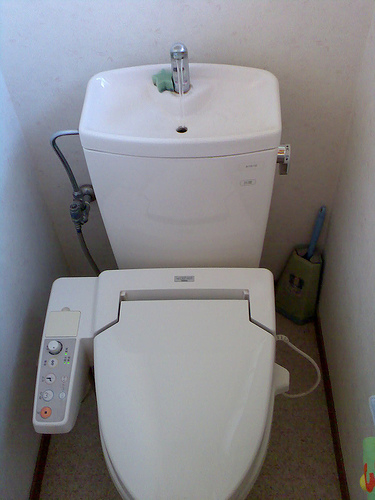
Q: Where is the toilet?
A: In a room.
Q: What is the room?
A: A toilet.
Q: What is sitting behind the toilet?
A: A toilet brush.